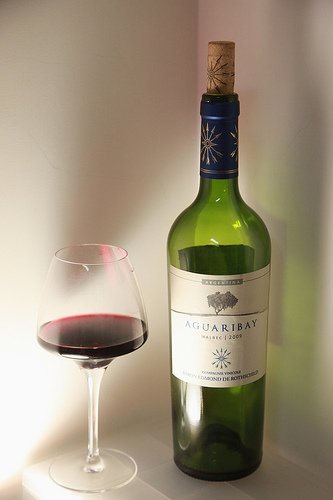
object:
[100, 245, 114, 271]
lipstick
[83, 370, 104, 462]
stem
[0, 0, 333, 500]
close-up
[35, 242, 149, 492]
empty glass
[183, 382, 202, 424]
reflection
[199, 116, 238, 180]
label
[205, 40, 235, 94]
cork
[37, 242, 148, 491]
glass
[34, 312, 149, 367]
wine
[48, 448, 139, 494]
base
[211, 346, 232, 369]
gold star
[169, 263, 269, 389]
label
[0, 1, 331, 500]
background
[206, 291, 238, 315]
logo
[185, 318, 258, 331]
manufacturer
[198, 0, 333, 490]
wall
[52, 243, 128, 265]
glass rim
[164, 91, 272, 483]
bottle